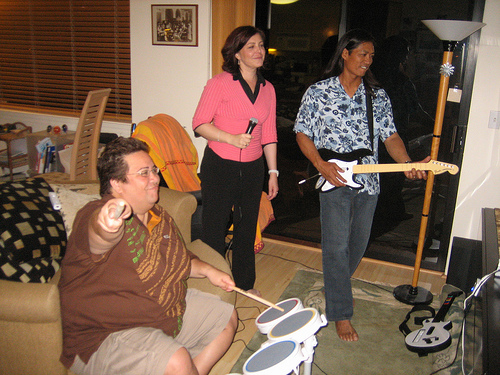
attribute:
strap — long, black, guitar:
[362, 82, 377, 155]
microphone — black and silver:
[242, 117, 258, 147]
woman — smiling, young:
[190, 22, 279, 290]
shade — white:
[420, 18, 484, 43]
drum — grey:
[251, 291, 304, 336]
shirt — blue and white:
[300, 87, 400, 216]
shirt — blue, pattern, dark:
[296, 71, 395, 192]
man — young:
[292, 31, 429, 338]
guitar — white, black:
[311, 152, 473, 194]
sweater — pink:
[187, 70, 277, 163]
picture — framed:
[146, 3, 201, 48]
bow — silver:
[434, 56, 458, 79]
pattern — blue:
[315, 107, 369, 157]